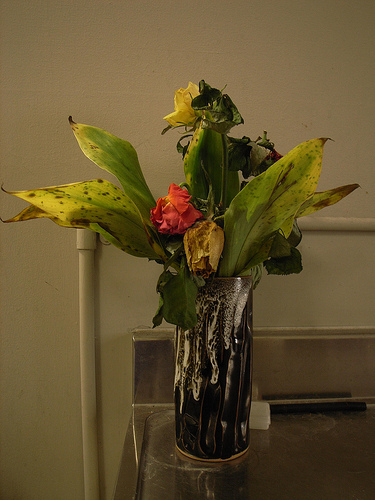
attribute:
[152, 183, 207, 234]
rose — drooping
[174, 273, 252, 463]
vase — black, round, white, cylindrical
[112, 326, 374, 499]
table — silver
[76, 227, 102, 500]
pipe — white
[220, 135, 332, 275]
leaf — gree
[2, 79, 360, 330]
flower — dry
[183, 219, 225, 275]
rose — yellow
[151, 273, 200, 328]
leave — withered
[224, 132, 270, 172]
leaves — dry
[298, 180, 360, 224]
leaves — brown